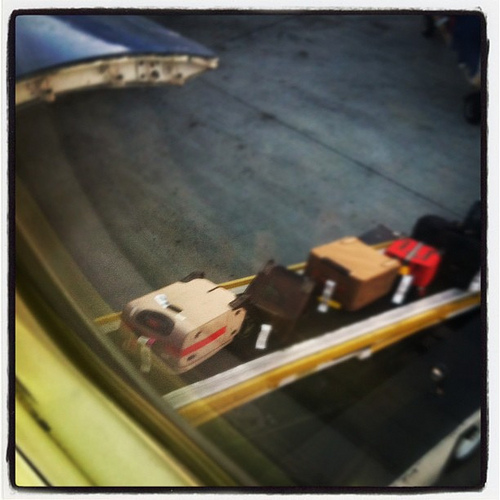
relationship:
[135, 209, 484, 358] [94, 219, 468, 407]
suitcases on conveyer belt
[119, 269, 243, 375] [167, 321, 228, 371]
suitcase has line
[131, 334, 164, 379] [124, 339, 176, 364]
tag on handle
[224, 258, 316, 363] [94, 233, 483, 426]
bag on conveyer belt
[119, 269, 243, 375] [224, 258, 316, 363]
suitcase next to bag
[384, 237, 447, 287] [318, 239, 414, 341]
bag next to suitcase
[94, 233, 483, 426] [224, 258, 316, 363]
conveyer belt for bag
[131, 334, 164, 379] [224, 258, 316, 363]
tag marking bag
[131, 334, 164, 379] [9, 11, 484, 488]
tag at air field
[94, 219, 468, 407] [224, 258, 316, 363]
conveyer belt of bag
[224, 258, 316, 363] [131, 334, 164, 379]
bag with tag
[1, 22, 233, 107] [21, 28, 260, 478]
door of airplane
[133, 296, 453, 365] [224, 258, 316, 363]
tags on bag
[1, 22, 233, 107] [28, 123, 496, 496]
door of cargo area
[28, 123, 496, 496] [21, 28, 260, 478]
cargo area of airplane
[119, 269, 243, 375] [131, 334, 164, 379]
suitcase with tag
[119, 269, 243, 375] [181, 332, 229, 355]
suitcase with trim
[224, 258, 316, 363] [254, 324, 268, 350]
bag with tag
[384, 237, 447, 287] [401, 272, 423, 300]
bag with tag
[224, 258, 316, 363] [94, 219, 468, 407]
bag on conveyer belt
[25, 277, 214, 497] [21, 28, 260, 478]
window frame of airplane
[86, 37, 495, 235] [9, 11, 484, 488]
pavement of air field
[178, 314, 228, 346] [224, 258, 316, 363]
stripe on bag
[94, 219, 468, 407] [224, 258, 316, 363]
conveyer belt loading bag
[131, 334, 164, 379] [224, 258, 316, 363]
tag on bag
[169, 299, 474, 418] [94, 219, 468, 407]
stripe on conveyer belt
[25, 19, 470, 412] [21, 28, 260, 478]
window of airplane